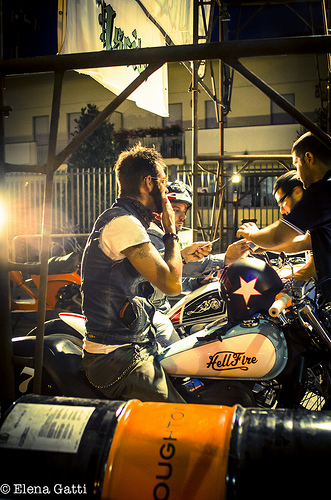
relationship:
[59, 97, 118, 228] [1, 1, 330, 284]
tree in front of building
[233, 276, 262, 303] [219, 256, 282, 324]
star on side of helmet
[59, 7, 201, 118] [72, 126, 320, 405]
banner above motorcyclist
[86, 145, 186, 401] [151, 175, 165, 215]
boy has beard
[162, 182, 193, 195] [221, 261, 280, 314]
goggles on helmet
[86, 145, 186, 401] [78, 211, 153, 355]
boy wearing shirt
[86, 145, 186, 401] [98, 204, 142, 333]
boy has vest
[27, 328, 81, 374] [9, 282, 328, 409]
seat on bike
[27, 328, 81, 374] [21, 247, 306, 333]
seat on bike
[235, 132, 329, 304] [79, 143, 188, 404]
men exchanging information with motorcyclist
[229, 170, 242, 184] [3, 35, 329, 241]
light on building